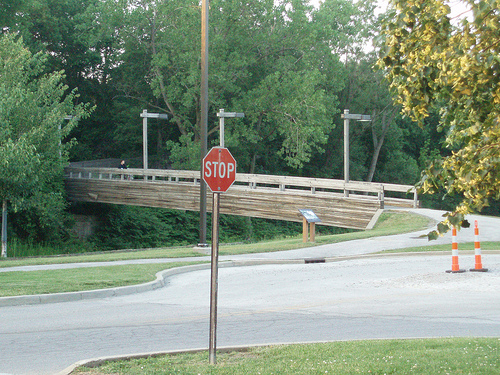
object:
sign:
[202, 147, 236, 191]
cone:
[450, 224, 460, 270]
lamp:
[358, 113, 373, 124]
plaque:
[300, 210, 316, 220]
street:
[276, 238, 406, 351]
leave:
[396, 41, 409, 55]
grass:
[119, 269, 133, 280]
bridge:
[213, 164, 377, 225]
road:
[332, 224, 407, 296]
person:
[117, 158, 130, 176]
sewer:
[305, 258, 323, 263]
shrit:
[118, 164, 129, 169]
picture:
[33, 14, 467, 349]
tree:
[356, 90, 391, 177]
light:
[229, 110, 247, 119]